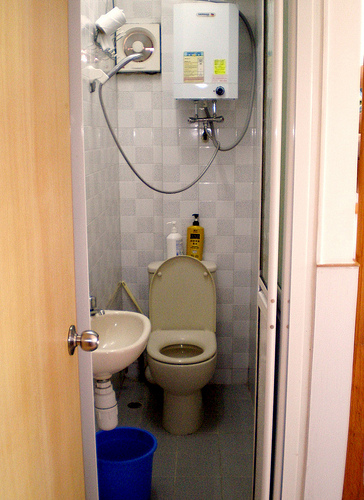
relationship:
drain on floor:
[120, 397, 147, 416] [105, 380, 258, 495]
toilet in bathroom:
[135, 248, 221, 438] [66, 20, 279, 473]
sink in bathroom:
[72, 303, 168, 429] [66, 20, 279, 473]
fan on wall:
[108, 21, 162, 77] [115, 12, 262, 275]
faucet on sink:
[83, 283, 114, 325] [72, 303, 168, 429]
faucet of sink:
[83, 283, 114, 325] [72, 303, 168, 429]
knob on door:
[71, 319, 100, 362] [9, 13, 99, 490]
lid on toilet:
[154, 251, 213, 332] [135, 248, 221, 438]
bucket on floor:
[97, 429, 153, 495] [105, 380, 258, 495]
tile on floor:
[127, 94, 172, 168] [105, 380, 258, 495]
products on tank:
[155, 219, 213, 258] [143, 256, 221, 295]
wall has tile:
[115, 12, 262, 275] [127, 94, 172, 168]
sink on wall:
[72, 303, 168, 429] [115, 12, 262, 275]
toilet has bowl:
[135, 248, 221, 438] [149, 360, 216, 392]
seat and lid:
[149, 330, 217, 364] [154, 251, 213, 332]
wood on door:
[9, 44, 58, 208] [9, 13, 99, 490]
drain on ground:
[120, 397, 147, 416] [105, 380, 258, 495]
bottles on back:
[157, 207, 209, 270] [146, 262, 218, 272]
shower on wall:
[86, 10, 126, 71] [115, 12, 262, 275]